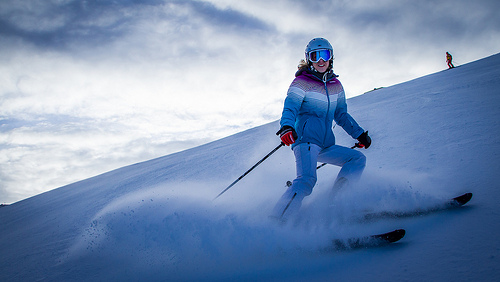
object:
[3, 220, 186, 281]
snow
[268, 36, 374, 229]
woman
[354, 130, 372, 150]
glove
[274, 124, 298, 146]
glove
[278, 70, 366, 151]
jacket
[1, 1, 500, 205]
clouds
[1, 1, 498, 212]
sky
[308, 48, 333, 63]
goggles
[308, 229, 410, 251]
ski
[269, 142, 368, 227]
pants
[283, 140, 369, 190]
ski pole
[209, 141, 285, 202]
ski pole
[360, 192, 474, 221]
ski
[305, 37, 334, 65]
helmet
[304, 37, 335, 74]
head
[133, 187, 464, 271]
snow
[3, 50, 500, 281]
mountain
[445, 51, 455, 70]
skier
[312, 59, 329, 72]
face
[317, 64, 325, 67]
smile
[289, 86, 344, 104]
stripe